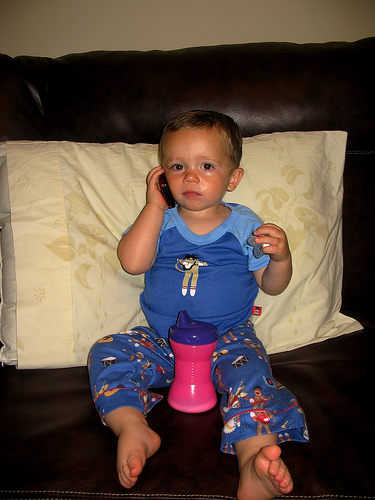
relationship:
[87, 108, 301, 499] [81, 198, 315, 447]
child in pajamas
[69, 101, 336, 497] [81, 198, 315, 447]
child in pajamas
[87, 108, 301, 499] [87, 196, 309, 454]
child on pajama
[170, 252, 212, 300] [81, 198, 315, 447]
picture on pajamas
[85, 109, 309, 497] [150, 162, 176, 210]
boy on phone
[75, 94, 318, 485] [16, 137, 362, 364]
boy on pillow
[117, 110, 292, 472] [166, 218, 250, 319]
boy on blue shirt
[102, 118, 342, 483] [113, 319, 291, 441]
boy wearing pants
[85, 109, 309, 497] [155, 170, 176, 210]
boy holding phone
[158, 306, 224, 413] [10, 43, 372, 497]
sippy cup on bed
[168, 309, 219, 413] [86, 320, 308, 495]
sippy cup between legs